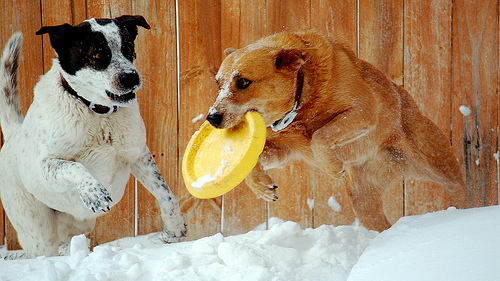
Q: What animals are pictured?
A: Dogs.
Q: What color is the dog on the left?
A: White and black.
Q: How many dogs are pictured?
A: Two.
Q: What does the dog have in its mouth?
A: A frisbee.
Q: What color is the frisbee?
A: Yellow.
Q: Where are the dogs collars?
A: On their necks.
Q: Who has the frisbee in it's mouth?
A: The brown dog.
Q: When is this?
A: Winter.